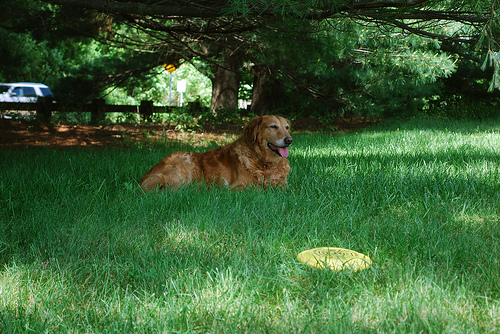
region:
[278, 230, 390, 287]
A frisbee is laying in the grass.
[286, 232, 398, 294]
The frisbee is yellow.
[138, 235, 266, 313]
The grass is green.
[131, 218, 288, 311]
The grass is long.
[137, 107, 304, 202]
The dog is laying in the grass.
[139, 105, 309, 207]
The dog is brown.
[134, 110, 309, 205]
The dog has it's tongue out.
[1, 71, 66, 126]
A car is in the background.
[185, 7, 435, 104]
Trees are in the background.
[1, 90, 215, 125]
A fence is in the background.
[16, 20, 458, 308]
a dog playing in the grass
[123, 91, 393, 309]
a yellow frisbee in front of the dog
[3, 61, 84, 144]
a white car near a fence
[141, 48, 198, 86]
a barely noticeable sign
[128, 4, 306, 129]
a tree trunk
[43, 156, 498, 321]
lush grass in a park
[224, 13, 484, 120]
green vegetation around the dog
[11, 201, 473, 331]
sunshine in the grass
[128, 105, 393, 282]
the dog is resting before another round of frisbee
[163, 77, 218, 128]
you can barely see this white sign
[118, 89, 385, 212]
the dog is brown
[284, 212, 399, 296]
the frisbee is yellow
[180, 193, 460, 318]
the frisbee is in the grass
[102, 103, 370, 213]
the dog is laying in the grass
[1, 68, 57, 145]
the vehicle is white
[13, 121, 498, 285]
the grass in long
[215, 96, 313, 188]
the dog's mouth is open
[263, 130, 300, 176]
the tongue is pink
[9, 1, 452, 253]
the dog is under trees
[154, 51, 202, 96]
a yellow sign behind the tree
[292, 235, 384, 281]
The yellow Frisbee in the grass.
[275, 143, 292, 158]
The pink tongue of the brown dog.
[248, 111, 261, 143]
The left floppy ear of the dog.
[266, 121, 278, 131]
The left eye of the dog.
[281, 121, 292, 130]
The right eye of the dog.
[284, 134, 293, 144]
The nose of the dog.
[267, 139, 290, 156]
The mouth of the dog.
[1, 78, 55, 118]
The white vehicle in the street.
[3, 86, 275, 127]
The wooden post fence in the background.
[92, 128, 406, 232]
The grass area the dog is laying down at.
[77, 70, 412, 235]
a dog laying in the grass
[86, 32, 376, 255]
a dog under a tree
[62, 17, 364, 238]
a dog laying in the shade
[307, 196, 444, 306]
a yellow freesbee on the ground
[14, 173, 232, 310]
tall green grass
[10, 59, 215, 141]
a short wooden fence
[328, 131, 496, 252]
a field of green grass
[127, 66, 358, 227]
a golden lab laying down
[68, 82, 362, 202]
a lab with his tounge out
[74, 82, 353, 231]
a dog laying down panting